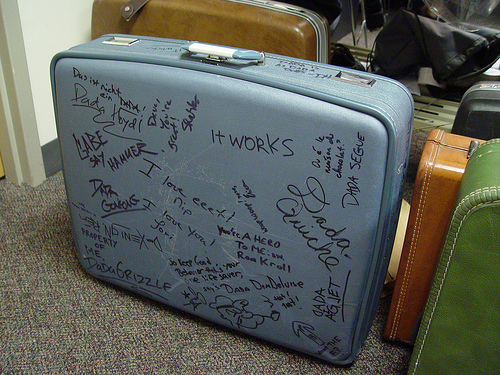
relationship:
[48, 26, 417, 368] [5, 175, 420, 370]
briefcase sitting on ground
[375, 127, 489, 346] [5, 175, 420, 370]
brown suitcase sitting on ground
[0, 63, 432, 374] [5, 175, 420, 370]
carpet covering ground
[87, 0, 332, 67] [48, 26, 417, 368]
luggage behind briefcase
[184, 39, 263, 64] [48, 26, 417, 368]
handle on briefcase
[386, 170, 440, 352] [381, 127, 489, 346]
stitching on brown suitcase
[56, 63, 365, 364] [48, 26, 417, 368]
signatures on briefcase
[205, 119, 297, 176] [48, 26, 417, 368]
writing on briefcase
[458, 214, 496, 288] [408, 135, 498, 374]
leather on suitcase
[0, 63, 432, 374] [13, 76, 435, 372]
carpet on floor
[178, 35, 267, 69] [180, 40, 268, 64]
handle on handle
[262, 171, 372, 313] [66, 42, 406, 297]
writing on suitcase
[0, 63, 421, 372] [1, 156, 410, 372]
carpet on floor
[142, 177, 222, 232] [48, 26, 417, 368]
writing on briefcase